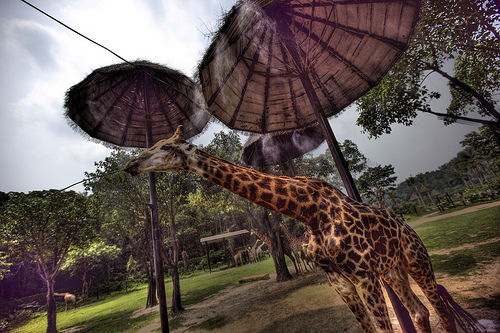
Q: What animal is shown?
A: Giraffe.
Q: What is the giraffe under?
A: Umbrella misters.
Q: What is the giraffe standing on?
A: Sand and dirt.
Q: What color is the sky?
A: Blue.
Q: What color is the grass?
A: Green.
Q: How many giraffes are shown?
A: Seven.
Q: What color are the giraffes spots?
A: Brown.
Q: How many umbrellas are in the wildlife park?
A: 3.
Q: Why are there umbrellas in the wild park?
A: To provide shade for the giraffes.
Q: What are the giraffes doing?
A: Standing under the umbrellas.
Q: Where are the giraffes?
A: Wildlife park.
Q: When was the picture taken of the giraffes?
A: During tourist vacation.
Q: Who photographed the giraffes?
A: Wild park visitor.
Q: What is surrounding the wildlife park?
A: Trees.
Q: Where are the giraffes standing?
A: On the grass.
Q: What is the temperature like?
A: Hot.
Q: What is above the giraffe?
A: Umbrellas.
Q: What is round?
A: Umbrellas.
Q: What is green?
A: Grass.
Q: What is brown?
A: Tree trunks.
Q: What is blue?
A: Sky.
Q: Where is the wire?
A: Above the umbrellas.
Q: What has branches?
A: Trees.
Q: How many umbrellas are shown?
A: 3.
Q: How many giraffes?
A: 7.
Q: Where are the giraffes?
A: Paddock.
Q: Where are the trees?
A: Behind the umbrellas.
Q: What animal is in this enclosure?
A: Giraffe.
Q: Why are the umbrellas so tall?
A: Because of the giraffe's long neck.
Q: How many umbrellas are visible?
A: 3.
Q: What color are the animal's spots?
A: Brown.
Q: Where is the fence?
A: Running around the enclosure.